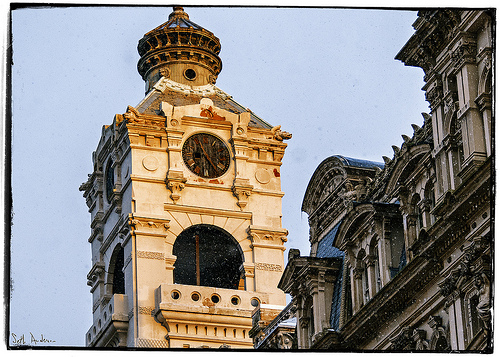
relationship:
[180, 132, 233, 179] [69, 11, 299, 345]
clock on tower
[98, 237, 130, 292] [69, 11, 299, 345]
arch on tower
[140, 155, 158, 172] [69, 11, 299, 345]
circle on tower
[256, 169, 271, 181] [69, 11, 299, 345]
circle on tower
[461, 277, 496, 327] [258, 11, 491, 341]
sculpture on th building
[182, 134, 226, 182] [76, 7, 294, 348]
clock on side of building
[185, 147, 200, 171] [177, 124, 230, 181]
numbers on side of clock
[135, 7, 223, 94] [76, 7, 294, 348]
dome on top of building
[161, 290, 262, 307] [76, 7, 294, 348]
holes on side of building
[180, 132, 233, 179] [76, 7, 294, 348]
clock on building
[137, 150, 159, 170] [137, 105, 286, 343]
circle on wall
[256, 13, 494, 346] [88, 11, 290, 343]
buildings by buildings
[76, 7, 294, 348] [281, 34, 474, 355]
building by buildings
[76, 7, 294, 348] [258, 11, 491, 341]
building by building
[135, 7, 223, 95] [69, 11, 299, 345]
dome adorning tower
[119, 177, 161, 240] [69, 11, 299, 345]
corner belonging to tower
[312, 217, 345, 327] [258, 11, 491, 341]
color livening up building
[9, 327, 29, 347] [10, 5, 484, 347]
seth printed on photo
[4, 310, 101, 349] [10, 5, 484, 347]
name printed on photo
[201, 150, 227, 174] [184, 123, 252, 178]
hand mounted on clock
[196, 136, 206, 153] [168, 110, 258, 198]
hand mounted on clock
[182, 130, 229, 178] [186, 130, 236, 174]
face adorning clock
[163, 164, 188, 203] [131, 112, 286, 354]
carving on wall